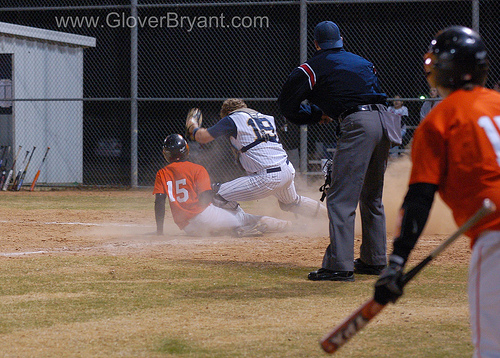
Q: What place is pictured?
A: It is a field.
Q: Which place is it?
A: It is a field.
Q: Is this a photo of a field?
A: Yes, it is showing a field.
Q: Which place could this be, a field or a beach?
A: It is a field.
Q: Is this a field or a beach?
A: It is a field.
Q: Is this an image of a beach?
A: No, the picture is showing a field.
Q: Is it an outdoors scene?
A: Yes, it is outdoors.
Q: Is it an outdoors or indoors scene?
A: It is outdoors.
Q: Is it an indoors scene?
A: No, it is outdoors.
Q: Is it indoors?
A: No, it is outdoors.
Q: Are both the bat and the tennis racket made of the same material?
A: Yes, both the bat and the tennis racket are made of wood.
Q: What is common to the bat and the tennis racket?
A: The material, both the bat and the tennis racket are wooden.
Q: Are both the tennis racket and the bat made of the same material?
A: Yes, both the tennis racket and the bat are made of wood.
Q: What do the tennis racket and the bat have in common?
A: The material, both the tennis racket and the bat are wooden.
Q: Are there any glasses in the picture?
A: No, there are no glasses.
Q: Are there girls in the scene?
A: No, there are no girls.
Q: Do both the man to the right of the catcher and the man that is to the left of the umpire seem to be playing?
A: Yes, both the man and the man are playing.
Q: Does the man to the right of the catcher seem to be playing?
A: Yes, the man is playing.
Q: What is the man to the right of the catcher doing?
A: The man is playing.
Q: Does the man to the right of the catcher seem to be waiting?
A: No, the man is playing.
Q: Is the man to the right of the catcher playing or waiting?
A: The man is playing.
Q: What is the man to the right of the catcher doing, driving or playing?
A: The man is playing.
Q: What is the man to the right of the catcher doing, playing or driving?
A: The man is playing.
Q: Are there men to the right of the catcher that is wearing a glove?
A: Yes, there is a man to the right of the catcher.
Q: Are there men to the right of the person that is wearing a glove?
A: Yes, there is a man to the right of the catcher.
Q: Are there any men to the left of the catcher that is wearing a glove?
A: No, the man is to the right of the catcher.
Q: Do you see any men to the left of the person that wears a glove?
A: No, the man is to the right of the catcher.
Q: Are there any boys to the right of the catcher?
A: No, there is a man to the right of the catcher.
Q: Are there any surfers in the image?
A: No, there are no surfers.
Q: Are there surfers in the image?
A: No, there are no surfers.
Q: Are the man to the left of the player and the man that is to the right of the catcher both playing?
A: Yes, both the man and the man are playing.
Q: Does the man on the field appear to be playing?
A: Yes, the man is playing.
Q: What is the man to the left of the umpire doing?
A: The man is playing.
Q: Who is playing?
A: The man is playing.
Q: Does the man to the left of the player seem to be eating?
A: No, the man is playing.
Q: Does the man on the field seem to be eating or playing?
A: The man is playing.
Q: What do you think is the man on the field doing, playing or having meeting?
A: The man is playing.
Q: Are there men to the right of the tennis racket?
A: Yes, there is a man to the right of the tennis racket.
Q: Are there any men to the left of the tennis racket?
A: No, the man is to the right of the tennis racket.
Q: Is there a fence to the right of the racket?
A: No, there is a man to the right of the racket.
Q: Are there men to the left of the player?
A: Yes, there is a man to the left of the player.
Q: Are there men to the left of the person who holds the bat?
A: Yes, there is a man to the left of the player.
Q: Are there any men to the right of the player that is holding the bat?
A: No, the man is to the left of the player.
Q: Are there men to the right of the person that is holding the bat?
A: No, the man is to the left of the player.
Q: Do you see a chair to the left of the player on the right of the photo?
A: No, there is a man to the left of the player.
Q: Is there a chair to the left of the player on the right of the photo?
A: No, there is a man to the left of the player.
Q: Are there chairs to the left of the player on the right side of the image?
A: No, there is a man to the left of the player.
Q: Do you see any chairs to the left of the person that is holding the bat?
A: No, there is a man to the left of the player.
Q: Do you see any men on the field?
A: Yes, there is a man on the field.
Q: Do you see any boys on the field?
A: No, there is a man on the field.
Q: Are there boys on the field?
A: No, there is a man on the field.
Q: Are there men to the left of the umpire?
A: Yes, there is a man to the left of the umpire.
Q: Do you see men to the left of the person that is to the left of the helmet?
A: Yes, there is a man to the left of the umpire.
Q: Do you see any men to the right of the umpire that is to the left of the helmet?
A: No, the man is to the left of the umpire.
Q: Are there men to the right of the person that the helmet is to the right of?
A: No, the man is to the left of the umpire.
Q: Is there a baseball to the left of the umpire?
A: No, there is a man to the left of the umpire.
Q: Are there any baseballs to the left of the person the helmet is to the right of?
A: No, there is a man to the left of the umpire.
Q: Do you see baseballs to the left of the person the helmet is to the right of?
A: No, there is a man to the left of the umpire.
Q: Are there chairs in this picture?
A: No, there are no chairs.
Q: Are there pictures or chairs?
A: No, there are no chairs or pictures.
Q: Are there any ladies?
A: No, there are no ladies.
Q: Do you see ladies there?
A: No, there are no ladies.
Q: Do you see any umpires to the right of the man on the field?
A: Yes, there is an umpire to the right of the man.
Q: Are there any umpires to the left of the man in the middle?
A: No, the umpire is to the right of the man.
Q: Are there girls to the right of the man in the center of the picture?
A: No, there is an umpire to the right of the man.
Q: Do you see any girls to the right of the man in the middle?
A: No, there is an umpire to the right of the man.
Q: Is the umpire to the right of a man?
A: Yes, the umpire is to the right of a man.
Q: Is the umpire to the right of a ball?
A: No, the umpire is to the right of a man.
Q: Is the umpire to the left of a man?
A: No, the umpire is to the right of a man.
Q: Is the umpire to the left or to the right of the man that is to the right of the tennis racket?
A: The umpire is to the right of the man.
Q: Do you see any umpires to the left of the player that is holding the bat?
A: Yes, there is an umpire to the left of the player.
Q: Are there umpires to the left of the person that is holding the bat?
A: Yes, there is an umpire to the left of the player.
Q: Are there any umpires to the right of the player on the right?
A: No, the umpire is to the left of the player.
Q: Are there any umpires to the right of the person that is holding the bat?
A: No, the umpire is to the left of the player.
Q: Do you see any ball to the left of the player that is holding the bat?
A: No, there is an umpire to the left of the player.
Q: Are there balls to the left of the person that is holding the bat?
A: No, there is an umpire to the left of the player.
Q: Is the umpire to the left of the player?
A: Yes, the umpire is to the left of the player.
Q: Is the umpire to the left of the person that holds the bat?
A: Yes, the umpire is to the left of the player.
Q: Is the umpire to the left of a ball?
A: No, the umpire is to the left of the player.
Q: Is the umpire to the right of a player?
A: No, the umpire is to the left of a player.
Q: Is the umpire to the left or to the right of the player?
A: The umpire is to the left of the player.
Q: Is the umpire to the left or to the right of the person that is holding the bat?
A: The umpire is to the left of the player.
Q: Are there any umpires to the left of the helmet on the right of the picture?
A: Yes, there is an umpire to the left of the helmet.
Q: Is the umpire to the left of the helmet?
A: Yes, the umpire is to the left of the helmet.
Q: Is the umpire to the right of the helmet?
A: No, the umpire is to the left of the helmet.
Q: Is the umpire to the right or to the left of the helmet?
A: The umpire is to the left of the helmet.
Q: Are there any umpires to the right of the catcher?
A: Yes, there is an umpire to the right of the catcher.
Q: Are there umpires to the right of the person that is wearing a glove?
A: Yes, there is an umpire to the right of the catcher.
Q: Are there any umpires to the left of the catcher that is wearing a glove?
A: No, the umpire is to the right of the catcher.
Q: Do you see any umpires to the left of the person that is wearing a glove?
A: No, the umpire is to the right of the catcher.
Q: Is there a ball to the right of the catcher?
A: No, there is an umpire to the right of the catcher.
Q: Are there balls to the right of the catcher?
A: No, there is an umpire to the right of the catcher.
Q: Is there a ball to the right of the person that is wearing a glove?
A: No, there is an umpire to the right of the catcher.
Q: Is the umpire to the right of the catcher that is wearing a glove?
A: Yes, the umpire is to the right of the catcher.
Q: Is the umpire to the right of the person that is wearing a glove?
A: Yes, the umpire is to the right of the catcher.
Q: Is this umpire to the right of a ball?
A: No, the umpire is to the right of the catcher.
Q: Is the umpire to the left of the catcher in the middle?
A: No, the umpire is to the right of the catcher.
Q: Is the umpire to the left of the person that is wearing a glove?
A: No, the umpire is to the right of the catcher.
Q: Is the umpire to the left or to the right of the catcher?
A: The umpire is to the right of the catcher.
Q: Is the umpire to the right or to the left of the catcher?
A: The umpire is to the right of the catcher.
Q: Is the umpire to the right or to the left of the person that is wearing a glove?
A: The umpire is to the right of the catcher.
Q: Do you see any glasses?
A: No, there are no glasses.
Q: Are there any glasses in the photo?
A: No, there are no glasses.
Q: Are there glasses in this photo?
A: No, there are no glasses.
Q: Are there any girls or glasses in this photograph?
A: No, there are no glasses or girls.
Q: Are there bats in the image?
A: Yes, there is a bat.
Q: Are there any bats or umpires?
A: Yes, there is a bat.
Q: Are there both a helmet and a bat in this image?
A: Yes, there are both a bat and a helmet.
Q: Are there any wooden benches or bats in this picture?
A: Yes, there is a wood bat.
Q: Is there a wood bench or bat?
A: Yes, there is a wood bat.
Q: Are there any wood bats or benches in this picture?
A: Yes, there is a wood bat.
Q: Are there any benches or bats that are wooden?
A: Yes, the bat is wooden.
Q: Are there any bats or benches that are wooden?
A: Yes, the bat is wooden.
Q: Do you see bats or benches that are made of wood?
A: Yes, the bat is made of wood.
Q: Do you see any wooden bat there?
A: Yes, there is a wood bat.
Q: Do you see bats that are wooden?
A: Yes, there is a bat that is wooden.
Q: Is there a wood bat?
A: Yes, there is a bat that is made of wood.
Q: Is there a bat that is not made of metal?
A: Yes, there is a bat that is made of wood.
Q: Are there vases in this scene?
A: No, there are no vases.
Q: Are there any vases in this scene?
A: No, there are no vases.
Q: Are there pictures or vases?
A: No, there are no vases or pictures.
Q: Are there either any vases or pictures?
A: No, there are no vases or pictures.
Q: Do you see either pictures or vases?
A: No, there are no vases or pictures.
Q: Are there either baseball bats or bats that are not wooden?
A: No, there is a bat but it is wooden.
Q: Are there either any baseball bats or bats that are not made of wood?
A: No, there is a bat but it is made of wood.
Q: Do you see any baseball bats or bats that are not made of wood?
A: No, there is a bat but it is made of wood.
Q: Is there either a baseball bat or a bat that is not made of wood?
A: No, there is a bat but it is made of wood.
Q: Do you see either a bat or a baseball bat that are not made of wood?
A: No, there is a bat but it is made of wood.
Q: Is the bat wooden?
A: Yes, the bat is wooden.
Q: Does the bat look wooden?
A: Yes, the bat is wooden.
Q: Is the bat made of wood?
A: Yes, the bat is made of wood.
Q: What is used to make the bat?
A: The bat is made of wood.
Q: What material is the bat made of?
A: The bat is made of wood.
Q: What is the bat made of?
A: The bat is made of wood.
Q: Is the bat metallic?
A: No, the bat is wooden.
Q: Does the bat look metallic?
A: No, the bat is wooden.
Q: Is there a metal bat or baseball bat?
A: No, there is a bat but it is wooden.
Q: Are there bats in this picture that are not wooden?
A: No, there is a bat but it is wooden.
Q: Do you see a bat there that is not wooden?
A: No, there is a bat but it is wooden.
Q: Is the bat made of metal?
A: No, the bat is made of wood.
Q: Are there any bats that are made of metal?
A: No, there is a bat but it is made of wood.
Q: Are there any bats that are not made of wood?
A: No, there is a bat but it is made of wood.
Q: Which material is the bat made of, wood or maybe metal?
A: The bat is made of wood.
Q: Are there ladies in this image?
A: No, there are no ladies.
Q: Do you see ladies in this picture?
A: No, there are no ladies.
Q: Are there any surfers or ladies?
A: No, there are no ladies or surfers.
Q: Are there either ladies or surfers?
A: No, there are no ladies or surfers.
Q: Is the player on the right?
A: Yes, the player is on the right of the image.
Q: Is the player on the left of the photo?
A: No, the player is on the right of the image.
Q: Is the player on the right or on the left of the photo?
A: The player is on the right of the image.